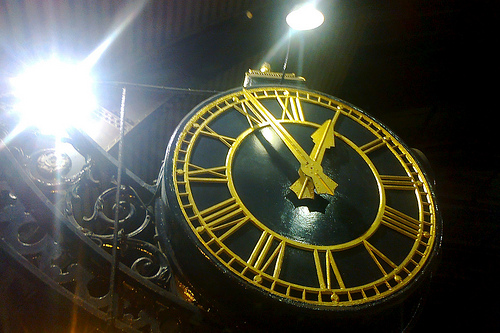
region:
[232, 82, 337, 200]
Minute hand of large clock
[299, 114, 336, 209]
Hour hand of large clock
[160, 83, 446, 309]
Face of large outdoor clock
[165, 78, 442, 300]
Clock face using Roman numeral's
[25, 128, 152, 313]
Decorative iron mount for outdoor clock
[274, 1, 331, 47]
Overhead outdoor light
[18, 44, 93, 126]
Overhead outdoor light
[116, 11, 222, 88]
Large steel support beam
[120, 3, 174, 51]
Sheet-metal for shelter roof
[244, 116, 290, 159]
Reflection of light on clock face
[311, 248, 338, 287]
part of a roman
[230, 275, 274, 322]
edge of a clock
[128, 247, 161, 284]
part of a metal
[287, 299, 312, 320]
edge of a clock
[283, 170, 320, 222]
part of a shade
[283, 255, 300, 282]
part of a clock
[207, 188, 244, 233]
part of a number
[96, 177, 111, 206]
part of a metal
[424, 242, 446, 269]
edge of a clock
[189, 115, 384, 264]
this is a clock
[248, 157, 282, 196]
the clock is black in color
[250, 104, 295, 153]
this is the minute hand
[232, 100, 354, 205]
the time is five minutes to one oclock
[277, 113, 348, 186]
the hands are yellow in color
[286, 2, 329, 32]
the light is on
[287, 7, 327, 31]
the light is bright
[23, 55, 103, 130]
the rays are white in color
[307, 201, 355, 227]
the inner is shiny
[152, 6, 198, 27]
the roof is of iron sheet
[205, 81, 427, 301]
clock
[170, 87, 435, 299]
yellow clock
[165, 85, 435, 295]
yellow and black clock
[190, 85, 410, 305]
large yellow and black clock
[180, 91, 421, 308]
large yellow and black clock with roman numerals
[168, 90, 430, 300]
roman numerals on large yellow and black clock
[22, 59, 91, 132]
bright white light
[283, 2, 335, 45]
bright white light in ceiling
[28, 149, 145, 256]
decorative black metal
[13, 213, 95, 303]
decorative black metal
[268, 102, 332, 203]
Gold hands on large clock.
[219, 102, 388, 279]
Gold numbers on large clock.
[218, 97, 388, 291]
Clock has black face.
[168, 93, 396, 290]
Clock is round in shape.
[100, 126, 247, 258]
Clock is connected to black object.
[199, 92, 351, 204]
Clock has 2 hands on face.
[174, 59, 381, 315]
Clock has 12 numbers on it.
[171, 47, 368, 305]
Numbers on clock are roman numerals.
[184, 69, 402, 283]
Face of clock is dark in color.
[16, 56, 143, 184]
Bright light shining in background.